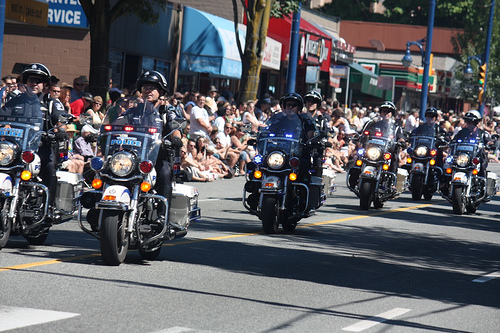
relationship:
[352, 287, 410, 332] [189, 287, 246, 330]
lines on road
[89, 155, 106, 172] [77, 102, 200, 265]
light on motorcycle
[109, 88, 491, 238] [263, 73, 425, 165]
cops wearing helmets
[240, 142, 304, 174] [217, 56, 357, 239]
light on motorcycle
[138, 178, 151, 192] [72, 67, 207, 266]
light on motorcycle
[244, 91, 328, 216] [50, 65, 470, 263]
cops on motorcycle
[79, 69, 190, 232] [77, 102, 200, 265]
cops on motorcycle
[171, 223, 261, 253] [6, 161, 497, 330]
line on road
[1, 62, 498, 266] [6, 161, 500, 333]
cops driving down road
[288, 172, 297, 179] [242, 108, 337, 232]
light on motorcycle